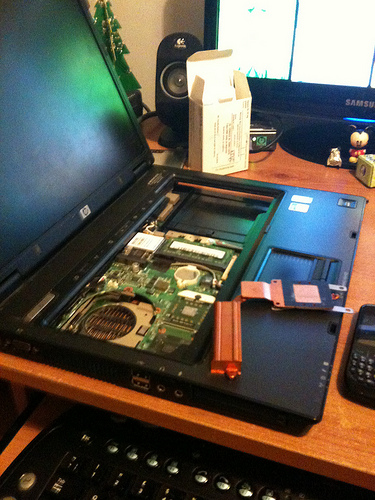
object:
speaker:
[155, 30, 203, 147]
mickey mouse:
[349, 125, 369, 163]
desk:
[244, 153, 324, 186]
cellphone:
[344, 303, 375, 402]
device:
[212, 300, 242, 381]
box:
[185, 48, 252, 176]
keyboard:
[0, 412, 304, 498]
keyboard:
[347, 342, 375, 385]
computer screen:
[0, 0, 142, 255]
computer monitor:
[214, 0, 374, 89]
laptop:
[1, 0, 366, 421]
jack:
[172, 387, 184, 399]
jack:
[156, 383, 166, 391]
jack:
[130, 371, 151, 391]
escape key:
[80, 434, 92, 447]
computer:
[203, 0, 375, 167]